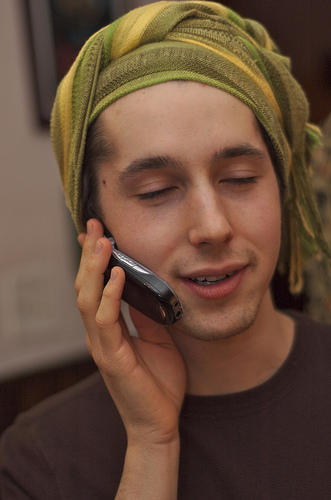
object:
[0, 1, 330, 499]
man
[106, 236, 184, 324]
phone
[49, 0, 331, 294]
cover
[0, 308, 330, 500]
shirt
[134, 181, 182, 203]
eye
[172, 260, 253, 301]
mouth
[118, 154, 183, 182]
eyebrow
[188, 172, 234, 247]
nose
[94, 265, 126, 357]
finger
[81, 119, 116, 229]
hair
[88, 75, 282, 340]
face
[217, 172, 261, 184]
eyes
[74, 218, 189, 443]
hand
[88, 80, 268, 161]
forehead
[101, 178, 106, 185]
mole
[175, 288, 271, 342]
stubble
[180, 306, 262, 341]
chin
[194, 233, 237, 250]
nostrils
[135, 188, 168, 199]
eyelashes